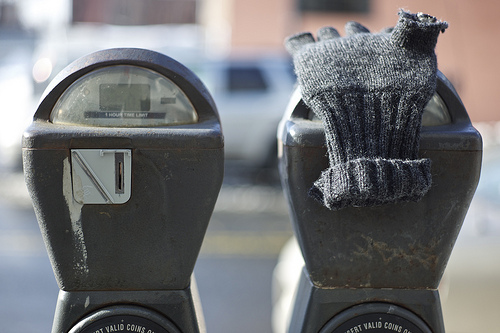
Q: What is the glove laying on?
A: A parking meter.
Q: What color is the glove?
A: Grey.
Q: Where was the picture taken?
A: At a parking meter.